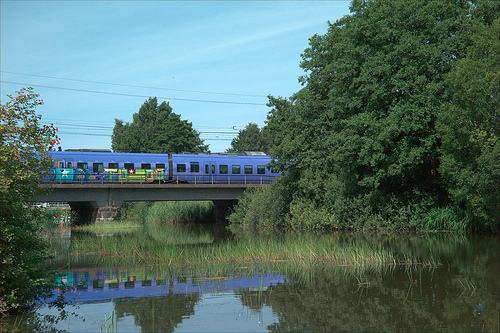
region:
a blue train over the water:
[14, 148, 315, 192]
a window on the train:
[184, 153, 207, 178]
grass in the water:
[88, 228, 423, 283]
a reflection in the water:
[0, 257, 302, 321]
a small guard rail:
[34, 170, 291, 190]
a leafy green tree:
[105, 86, 226, 154]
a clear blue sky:
[0, 0, 368, 153]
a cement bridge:
[14, 172, 307, 228]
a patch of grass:
[424, 196, 481, 238]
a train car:
[167, 148, 309, 190]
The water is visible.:
[234, 273, 334, 328]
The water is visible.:
[261, 291, 292, 312]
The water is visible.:
[353, 313, 389, 328]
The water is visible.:
[268, 290, 383, 332]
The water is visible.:
[292, 268, 433, 332]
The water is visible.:
[290, 311, 360, 329]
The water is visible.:
[273, 262, 415, 308]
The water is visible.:
[213, 255, 300, 327]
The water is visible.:
[219, 281, 245, 308]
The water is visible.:
[253, 294, 328, 328]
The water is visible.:
[264, 283, 316, 321]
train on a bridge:
[80, 104, 307, 264]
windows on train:
[102, 155, 139, 177]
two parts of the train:
[101, 144, 254, 200]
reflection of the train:
[108, 256, 213, 321]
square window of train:
[171, 153, 191, 182]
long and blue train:
[59, 131, 254, 233]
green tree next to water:
[323, 81, 420, 182]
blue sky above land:
[138, 0, 222, 78]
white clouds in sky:
[112, 49, 187, 107]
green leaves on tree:
[346, 16, 438, 121]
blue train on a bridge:
[13, 141, 293, 208]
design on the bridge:
[99, 165, 169, 182]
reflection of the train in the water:
[26, 261, 297, 306]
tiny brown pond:
[31, 248, 483, 331]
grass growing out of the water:
[113, 244, 183, 292]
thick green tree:
[251, 3, 497, 207]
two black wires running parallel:
[0, 65, 287, 112]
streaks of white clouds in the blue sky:
[133, 16, 294, 73]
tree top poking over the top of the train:
[103, 91, 204, 163]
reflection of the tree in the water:
[148, 219, 213, 248]